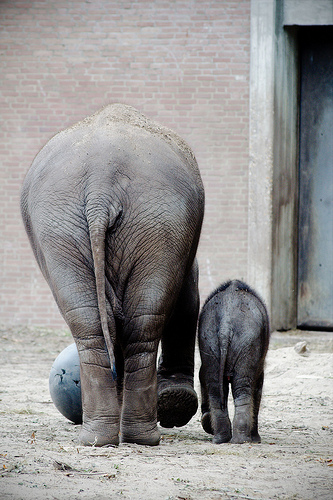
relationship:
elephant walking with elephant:
[195, 278, 270, 443] [19, 99, 208, 447]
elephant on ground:
[195, 278, 270, 443] [4, 326, 326, 496]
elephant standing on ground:
[19, 99, 208, 447] [4, 326, 326, 496]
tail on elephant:
[216, 320, 231, 408] [195, 278, 270, 443]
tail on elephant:
[83, 195, 122, 376] [19, 99, 208, 447]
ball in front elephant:
[49, 342, 84, 421] [19, 99, 208, 447]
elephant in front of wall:
[198, 278, 270, 446] [7, 2, 251, 328]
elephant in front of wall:
[19, 99, 208, 447] [7, 2, 251, 328]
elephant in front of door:
[195, 278, 270, 443] [295, 29, 331, 328]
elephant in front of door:
[19, 99, 208, 447] [295, 29, 331, 328]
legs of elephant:
[199, 362, 261, 444] [195, 278, 270, 443]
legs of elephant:
[40, 228, 179, 443] [19, 99, 208, 447]